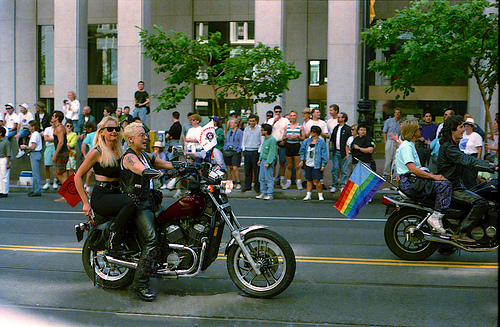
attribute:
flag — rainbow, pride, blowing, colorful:
[332, 160, 386, 220]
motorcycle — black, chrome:
[383, 164, 499, 259]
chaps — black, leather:
[131, 203, 166, 287]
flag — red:
[59, 173, 89, 207]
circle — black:
[67, 182, 81, 195]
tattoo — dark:
[126, 156, 136, 167]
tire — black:
[81, 231, 137, 291]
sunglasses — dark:
[101, 126, 122, 131]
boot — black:
[132, 284, 157, 301]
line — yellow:
[2, 244, 500, 270]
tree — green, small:
[135, 25, 301, 129]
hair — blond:
[93, 115, 125, 168]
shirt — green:
[258, 134, 277, 165]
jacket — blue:
[299, 137, 328, 168]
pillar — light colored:
[326, 1, 364, 131]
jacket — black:
[437, 141, 495, 192]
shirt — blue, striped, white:
[287, 122, 303, 144]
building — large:
[1, 1, 500, 160]